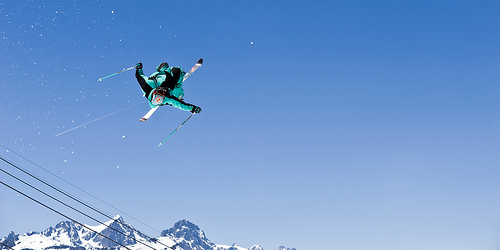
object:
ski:
[182, 58, 204, 84]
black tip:
[197, 58, 204, 65]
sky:
[2, 3, 494, 248]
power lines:
[2, 157, 162, 249]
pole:
[155, 112, 197, 148]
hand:
[189, 105, 202, 114]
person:
[134, 58, 203, 113]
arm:
[135, 68, 149, 94]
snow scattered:
[49, 5, 163, 58]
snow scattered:
[241, 32, 262, 51]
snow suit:
[134, 67, 197, 113]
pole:
[96, 63, 141, 82]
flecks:
[92, 71, 95, 73]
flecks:
[59, 147, 85, 173]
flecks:
[11, 9, 44, 49]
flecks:
[8, 116, 38, 144]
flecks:
[115, 135, 138, 171]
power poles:
[51, 100, 149, 137]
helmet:
[150, 87, 166, 105]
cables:
[0, 142, 180, 250]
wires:
[0, 146, 184, 250]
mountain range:
[4, 216, 262, 248]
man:
[134, 57, 202, 114]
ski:
[139, 105, 161, 122]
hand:
[134, 62, 143, 69]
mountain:
[0, 215, 238, 250]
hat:
[151, 87, 167, 105]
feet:
[154, 57, 189, 84]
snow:
[27, 235, 42, 247]